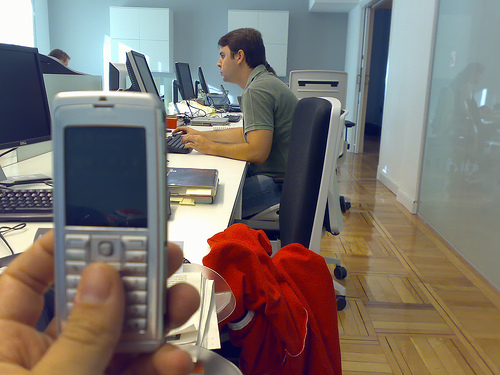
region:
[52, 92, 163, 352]
this is a phone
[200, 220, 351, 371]
this is a red cloth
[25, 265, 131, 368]
the finger of a man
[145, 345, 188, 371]
the finger of a man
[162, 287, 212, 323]
the finger of a man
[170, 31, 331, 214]
this is a person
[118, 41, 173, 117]
the screen of a computer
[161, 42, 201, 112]
the screen of a computer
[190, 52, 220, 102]
the screen of a computer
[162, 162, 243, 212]
two books on the table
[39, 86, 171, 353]
Cell phone being held.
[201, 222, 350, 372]
Red jacket on the chair.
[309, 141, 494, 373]
Parkay flooring on the floor.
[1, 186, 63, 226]
Keyboard on the desk.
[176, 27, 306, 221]
Man at the computer.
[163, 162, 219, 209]
Book on the desk.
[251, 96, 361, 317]
Chairs with rollers in the office.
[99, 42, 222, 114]
Computer monitors on the table.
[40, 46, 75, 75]
Man in the background.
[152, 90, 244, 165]
Electronic equipment on the table.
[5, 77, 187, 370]
person holding a phone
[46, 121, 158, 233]
reflection in the cellphone glass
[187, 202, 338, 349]
jacket on a chair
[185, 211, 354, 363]
the jacket is red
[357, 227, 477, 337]
the floors are tan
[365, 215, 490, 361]
the floors are made of wood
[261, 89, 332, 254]
the chair cushion is black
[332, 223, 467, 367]
the shape on the floor is square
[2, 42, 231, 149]
a row of monitors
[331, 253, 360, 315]
the wheels are black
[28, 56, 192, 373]
a person holding a cell phone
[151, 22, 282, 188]
a man sitting at a computer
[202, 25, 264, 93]
a man with brown hair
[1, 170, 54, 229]
a black computer keyboard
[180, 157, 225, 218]
two books on a table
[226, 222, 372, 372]
a red jacket over a chair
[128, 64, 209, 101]
three computer monitors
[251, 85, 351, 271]
a desk chair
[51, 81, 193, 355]
a silver cell phone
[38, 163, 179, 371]
a person's thumb on a cell phone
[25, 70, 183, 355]
Person holding an old model cell phone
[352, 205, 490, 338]
Wooden floors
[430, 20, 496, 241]
Reflection of people sitting at their desks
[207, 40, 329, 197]
Man wearing a green polo shirt looking at his monitor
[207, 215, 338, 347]
A red shirt on the arm of a chair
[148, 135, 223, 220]
Two books on the desk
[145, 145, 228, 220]
Library books on the desk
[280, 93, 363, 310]
Black and cream rolling office chairs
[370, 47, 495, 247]
Opaque glass divider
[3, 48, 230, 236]
A row of flatscreen monitors and keyboards